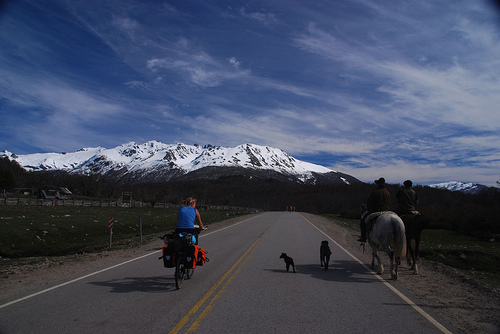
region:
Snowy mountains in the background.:
[16, 127, 356, 186]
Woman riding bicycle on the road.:
[154, 187, 207, 294]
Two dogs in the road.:
[258, 224, 350, 288]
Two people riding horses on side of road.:
[357, 166, 437, 293]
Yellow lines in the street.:
[207, 235, 265, 308]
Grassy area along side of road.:
[2, 207, 144, 252]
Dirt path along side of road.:
[389, 270, 499, 330]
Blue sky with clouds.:
[14, 11, 498, 134]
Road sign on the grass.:
[100, 212, 125, 260]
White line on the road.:
[366, 287, 456, 332]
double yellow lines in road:
[154, 275, 251, 314]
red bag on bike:
[189, 235, 220, 280]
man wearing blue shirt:
[172, 201, 215, 237]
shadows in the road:
[280, 244, 424, 285]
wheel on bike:
[152, 257, 214, 283]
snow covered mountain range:
[99, 112, 249, 164]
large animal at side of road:
[359, 196, 422, 302]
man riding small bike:
[125, 186, 230, 291]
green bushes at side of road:
[23, 177, 100, 242]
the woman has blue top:
[166, 204, 222, 239]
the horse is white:
[358, 205, 403, 252]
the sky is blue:
[64, 78, 462, 121]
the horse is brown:
[400, 204, 436, 264]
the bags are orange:
[149, 232, 224, 268]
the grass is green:
[46, 202, 116, 225]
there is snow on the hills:
[100, 134, 285, 180]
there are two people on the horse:
[303, 134, 470, 272]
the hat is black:
[366, 163, 398, 190]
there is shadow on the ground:
[298, 248, 372, 298]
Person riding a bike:
[152, 188, 227, 297]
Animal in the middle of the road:
[275, 241, 305, 285]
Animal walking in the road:
[309, 226, 343, 281]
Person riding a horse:
[349, 168, 413, 286]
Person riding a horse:
[394, 158, 427, 285]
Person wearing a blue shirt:
[156, 181, 213, 295]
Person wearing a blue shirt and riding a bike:
[157, 178, 234, 292]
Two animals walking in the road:
[245, 226, 350, 291]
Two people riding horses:
[348, 163, 444, 295]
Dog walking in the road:
[314, 228, 345, 281]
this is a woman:
[172, 195, 207, 250]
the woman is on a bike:
[157, 218, 210, 287]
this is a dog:
[305, 239, 335, 274]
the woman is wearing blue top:
[179, 213, 195, 230]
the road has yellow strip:
[220, 235, 264, 302]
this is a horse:
[356, 209, 411, 274]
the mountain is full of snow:
[116, 146, 280, 169]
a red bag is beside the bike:
[190, 246, 207, 264]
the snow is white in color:
[195, 143, 255, 163]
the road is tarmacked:
[258, 215, 286, 242]